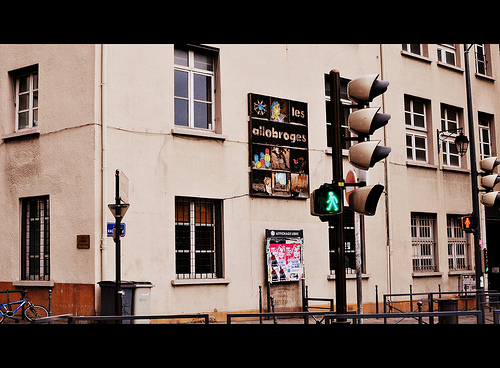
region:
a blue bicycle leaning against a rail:
[3, 291, 48, 318]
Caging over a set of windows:
[173, 199, 223, 278]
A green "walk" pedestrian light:
[318, 186, 340, 214]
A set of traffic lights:
[332, 82, 392, 212]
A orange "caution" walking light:
[465, 213, 474, 230]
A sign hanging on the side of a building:
[251, 87, 310, 215]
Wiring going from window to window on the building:
[113, 111, 170, 151]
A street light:
[439, 125, 471, 170]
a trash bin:
[98, 272, 164, 322]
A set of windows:
[5, 63, 42, 142]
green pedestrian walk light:
[313, 185, 340, 223]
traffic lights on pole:
[325, 56, 387, 245]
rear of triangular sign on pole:
[103, 197, 134, 230]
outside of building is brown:
[125, 129, 155, 205]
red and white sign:
[233, 210, 298, 287]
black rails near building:
[373, 282, 493, 324]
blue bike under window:
[3, 290, 39, 325]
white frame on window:
[178, 207, 223, 282]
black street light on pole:
[441, 112, 473, 164]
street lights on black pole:
[301, 75, 363, 323]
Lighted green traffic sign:
[312, 180, 346, 220]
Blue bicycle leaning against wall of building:
[0, 284, 55, 322]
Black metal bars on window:
[173, 198, 223, 280]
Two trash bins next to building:
[92, 277, 154, 327]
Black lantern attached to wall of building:
[430, 122, 470, 159]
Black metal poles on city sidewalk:
[254, 285, 479, 319]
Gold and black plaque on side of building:
[74, 232, 91, 252]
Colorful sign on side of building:
[249, 89, 311, 199]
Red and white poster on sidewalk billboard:
[261, 226, 308, 319]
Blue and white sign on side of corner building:
[104, 219, 130, 240]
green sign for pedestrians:
[319, 184, 351, 226]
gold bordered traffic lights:
[342, 77, 391, 217]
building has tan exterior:
[104, 90, 269, 242]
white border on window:
[157, 162, 239, 302]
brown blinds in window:
[172, 197, 212, 235]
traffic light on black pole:
[295, 77, 357, 316]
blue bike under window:
[0, 290, 52, 312]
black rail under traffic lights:
[262, 282, 491, 351]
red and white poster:
[270, 242, 299, 288]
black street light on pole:
[437, 125, 471, 212]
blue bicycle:
[0, 279, 64, 331]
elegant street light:
[433, 125, 472, 171]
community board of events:
[260, 230, 309, 287]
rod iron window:
[174, 198, 230, 286]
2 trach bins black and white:
[98, 278, 158, 335]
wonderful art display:
[246, 92, 309, 199]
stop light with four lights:
[338, 75, 396, 214]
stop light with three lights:
[473, 152, 498, 204]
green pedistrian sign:
[313, 183, 346, 218]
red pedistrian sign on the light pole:
[460, 213, 474, 233]